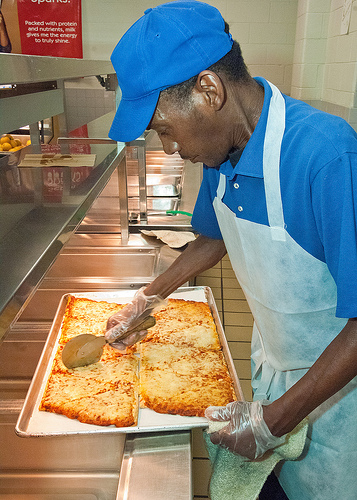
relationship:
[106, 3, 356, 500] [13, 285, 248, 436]
man holding tray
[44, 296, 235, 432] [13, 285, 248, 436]
pizza on tray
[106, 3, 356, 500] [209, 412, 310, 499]
man holding towel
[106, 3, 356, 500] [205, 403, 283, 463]
man wearing glove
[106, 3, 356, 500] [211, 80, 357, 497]
man wearing apron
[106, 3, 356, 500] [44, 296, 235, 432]
man slicing pizza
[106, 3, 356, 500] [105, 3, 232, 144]
man wearing hat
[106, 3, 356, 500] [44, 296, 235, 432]
man cutting pizza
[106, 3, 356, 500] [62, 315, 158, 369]
man holding cutter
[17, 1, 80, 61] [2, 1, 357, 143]
sign on wall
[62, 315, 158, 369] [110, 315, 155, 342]
cutter has handle